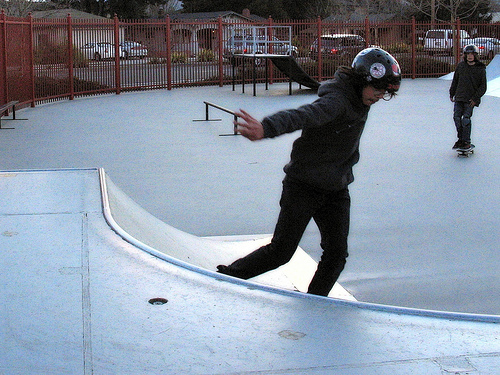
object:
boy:
[448, 42, 487, 152]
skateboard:
[452, 137, 478, 157]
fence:
[4, 14, 499, 121]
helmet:
[350, 41, 401, 92]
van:
[423, 30, 472, 54]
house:
[6, 3, 135, 59]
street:
[0, 54, 500, 105]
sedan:
[82, 34, 124, 64]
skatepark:
[0, 3, 500, 375]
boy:
[213, 47, 400, 297]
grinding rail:
[195, 99, 245, 136]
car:
[121, 36, 151, 59]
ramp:
[3, 169, 498, 374]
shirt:
[259, 66, 371, 193]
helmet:
[460, 45, 480, 54]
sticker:
[371, 61, 388, 81]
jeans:
[216, 185, 353, 296]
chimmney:
[238, 6, 248, 22]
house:
[165, 8, 268, 75]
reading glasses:
[369, 86, 394, 102]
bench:
[0, 94, 24, 142]